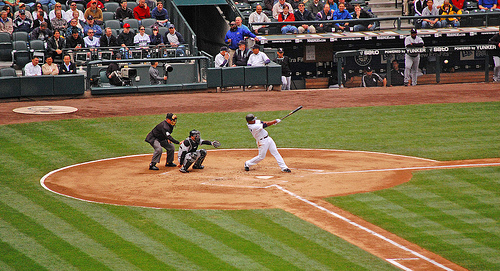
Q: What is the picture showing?
A: It is showing a field.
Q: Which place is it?
A: It is a field.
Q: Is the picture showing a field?
A: Yes, it is showing a field.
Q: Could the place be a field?
A: Yes, it is a field.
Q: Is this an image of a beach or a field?
A: It is showing a field.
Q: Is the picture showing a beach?
A: No, the picture is showing a field.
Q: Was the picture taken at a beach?
A: No, the picture was taken in a field.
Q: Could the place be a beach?
A: No, it is a field.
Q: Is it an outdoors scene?
A: Yes, it is outdoors.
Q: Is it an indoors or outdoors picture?
A: It is outdoors.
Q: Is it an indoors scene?
A: No, it is outdoors.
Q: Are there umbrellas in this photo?
A: No, there are no umbrellas.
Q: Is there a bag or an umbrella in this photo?
A: No, there are no umbrellas or bags.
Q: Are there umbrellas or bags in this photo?
A: No, there are no umbrellas or bags.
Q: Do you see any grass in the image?
A: Yes, there is grass.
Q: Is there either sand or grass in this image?
A: Yes, there is grass.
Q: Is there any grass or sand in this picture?
A: Yes, there is grass.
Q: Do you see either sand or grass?
A: Yes, there is grass.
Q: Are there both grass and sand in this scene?
A: No, there is grass but no sand.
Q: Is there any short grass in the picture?
A: Yes, there is short grass.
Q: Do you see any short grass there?
A: Yes, there is short grass.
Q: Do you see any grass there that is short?
A: Yes, there is grass that is short.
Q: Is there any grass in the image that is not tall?
A: Yes, there is short grass.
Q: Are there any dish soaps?
A: No, there are no dish soaps.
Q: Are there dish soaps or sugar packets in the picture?
A: No, there are no dish soaps or sugar packets.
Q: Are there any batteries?
A: No, there are no batteries.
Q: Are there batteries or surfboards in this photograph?
A: No, there are no batteries or surfboards.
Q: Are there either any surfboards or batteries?
A: No, there are no batteries or surfboards.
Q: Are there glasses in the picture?
A: No, there are no glasses.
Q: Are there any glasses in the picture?
A: No, there are no glasses.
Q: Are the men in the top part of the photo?
A: Yes, the men are in the top of the image.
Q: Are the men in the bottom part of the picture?
A: No, the men are in the top of the image.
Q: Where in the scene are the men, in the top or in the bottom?
A: The men are in the top of the image.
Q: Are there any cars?
A: No, there are no cars.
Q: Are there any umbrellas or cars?
A: No, there are no cars or umbrellas.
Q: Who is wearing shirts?
A: The people are wearing shirts.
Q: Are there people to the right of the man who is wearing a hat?
A: Yes, there are people to the right of the man.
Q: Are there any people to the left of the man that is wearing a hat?
A: No, the people are to the right of the man.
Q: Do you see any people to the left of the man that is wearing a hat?
A: No, the people are to the right of the man.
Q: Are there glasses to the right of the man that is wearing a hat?
A: No, there are people to the right of the man.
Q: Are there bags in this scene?
A: No, there are no bags.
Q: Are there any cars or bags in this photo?
A: No, there are no bags or cars.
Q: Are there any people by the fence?
A: Yes, there is a person by the fence.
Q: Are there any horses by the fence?
A: No, there is a person by the fence.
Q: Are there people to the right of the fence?
A: Yes, there is a person to the right of the fence.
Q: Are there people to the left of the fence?
A: No, the person is to the right of the fence.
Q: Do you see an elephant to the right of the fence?
A: No, there is a person to the right of the fence.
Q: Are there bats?
A: Yes, there is a bat.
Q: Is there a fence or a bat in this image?
A: Yes, there is a bat.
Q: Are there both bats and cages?
A: No, there is a bat but no cages.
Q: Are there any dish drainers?
A: No, there are no dish drainers.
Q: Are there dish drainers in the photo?
A: No, there are no dish drainers.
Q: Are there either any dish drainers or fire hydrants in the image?
A: No, there are no dish drainers or fire hydrants.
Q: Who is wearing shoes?
A: The umpire is wearing shoes.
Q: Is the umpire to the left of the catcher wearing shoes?
A: Yes, the umpire is wearing shoes.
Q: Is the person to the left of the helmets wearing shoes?
A: Yes, the umpire is wearing shoes.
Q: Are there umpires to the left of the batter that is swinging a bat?
A: Yes, there is an umpire to the left of the batter.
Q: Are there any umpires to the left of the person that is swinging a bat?
A: Yes, there is an umpire to the left of the batter.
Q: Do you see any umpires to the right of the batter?
A: No, the umpire is to the left of the batter.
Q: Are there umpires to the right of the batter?
A: No, the umpire is to the left of the batter.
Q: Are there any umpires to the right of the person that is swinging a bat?
A: No, the umpire is to the left of the batter.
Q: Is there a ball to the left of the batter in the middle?
A: No, there is an umpire to the left of the batter.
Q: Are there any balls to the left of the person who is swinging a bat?
A: No, there is an umpire to the left of the batter.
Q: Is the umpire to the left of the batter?
A: Yes, the umpire is to the left of the batter.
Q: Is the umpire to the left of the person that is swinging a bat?
A: Yes, the umpire is to the left of the batter.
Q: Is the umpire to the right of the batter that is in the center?
A: No, the umpire is to the left of the batter.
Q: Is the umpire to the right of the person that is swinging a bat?
A: No, the umpire is to the left of the batter.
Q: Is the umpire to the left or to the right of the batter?
A: The umpire is to the left of the batter.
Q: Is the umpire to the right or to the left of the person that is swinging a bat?
A: The umpire is to the left of the batter.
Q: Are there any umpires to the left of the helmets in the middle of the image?
A: Yes, there is an umpire to the left of the helmets.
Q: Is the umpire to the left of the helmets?
A: Yes, the umpire is to the left of the helmets.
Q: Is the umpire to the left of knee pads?
A: No, the umpire is to the left of the helmets.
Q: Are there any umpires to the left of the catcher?
A: Yes, there is an umpire to the left of the catcher.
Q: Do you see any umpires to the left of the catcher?
A: Yes, there is an umpire to the left of the catcher.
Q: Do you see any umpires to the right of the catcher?
A: No, the umpire is to the left of the catcher.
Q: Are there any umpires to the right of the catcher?
A: No, the umpire is to the left of the catcher.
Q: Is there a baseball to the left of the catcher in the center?
A: No, there is an umpire to the left of the catcher.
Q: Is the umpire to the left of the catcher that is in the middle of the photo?
A: Yes, the umpire is to the left of the catcher.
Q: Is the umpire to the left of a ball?
A: No, the umpire is to the left of the catcher.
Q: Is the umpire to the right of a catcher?
A: No, the umpire is to the left of a catcher.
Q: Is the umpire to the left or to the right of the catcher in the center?
A: The umpire is to the left of the catcher.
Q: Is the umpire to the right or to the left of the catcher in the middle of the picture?
A: The umpire is to the left of the catcher.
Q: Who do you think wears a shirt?
A: The umpire wears a shirt.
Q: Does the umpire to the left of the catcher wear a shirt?
A: Yes, the umpire wears a shirt.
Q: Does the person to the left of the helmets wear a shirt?
A: Yes, the umpire wears a shirt.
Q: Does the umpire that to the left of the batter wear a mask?
A: No, the umpire wears a shirt.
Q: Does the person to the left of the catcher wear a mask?
A: No, the umpire wears a shirt.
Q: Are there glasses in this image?
A: No, there are no glasses.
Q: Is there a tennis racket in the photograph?
A: No, there are no rackets.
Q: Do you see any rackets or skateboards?
A: No, there are no rackets or skateboards.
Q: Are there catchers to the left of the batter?
A: Yes, there is a catcher to the left of the batter.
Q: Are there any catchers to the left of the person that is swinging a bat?
A: Yes, there is a catcher to the left of the batter.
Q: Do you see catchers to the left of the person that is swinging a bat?
A: Yes, there is a catcher to the left of the batter.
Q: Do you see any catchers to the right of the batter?
A: No, the catcher is to the left of the batter.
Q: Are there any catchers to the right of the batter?
A: No, the catcher is to the left of the batter.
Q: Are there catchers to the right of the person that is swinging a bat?
A: No, the catcher is to the left of the batter.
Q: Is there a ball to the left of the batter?
A: No, there is a catcher to the left of the batter.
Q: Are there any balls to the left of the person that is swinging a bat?
A: No, there is a catcher to the left of the batter.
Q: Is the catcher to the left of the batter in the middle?
A: Yes, the catcher is to the left of the batter.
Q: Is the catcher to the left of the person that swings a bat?
A: Yes, the catcher is to the left of the batter.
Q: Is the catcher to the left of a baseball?
A: No, the catcher is to the left of the batter.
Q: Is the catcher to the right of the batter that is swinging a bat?
A: No, the catcher is to the left of the batter.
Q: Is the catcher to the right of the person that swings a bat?
A: No, the catcher is to the left of the batter.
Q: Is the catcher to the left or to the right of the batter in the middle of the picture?
A: The catcher is to the left of the batter.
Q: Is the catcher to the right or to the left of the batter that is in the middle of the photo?
A: The catcher is to the left of the batter.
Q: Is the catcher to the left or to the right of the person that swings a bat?
A: The catcher is to the left of the batter.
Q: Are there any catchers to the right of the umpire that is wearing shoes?
A: Yes, there is a catcher to the right of the umpire.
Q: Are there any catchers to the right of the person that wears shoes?
A: Yes, there is a catcher to the right of the umpire.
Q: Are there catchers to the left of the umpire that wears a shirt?
A: No, the catcher is to the right of the umpire.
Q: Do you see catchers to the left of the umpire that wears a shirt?
A: No, the catcher is to the right of the umpire.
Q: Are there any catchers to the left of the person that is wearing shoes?
A: No, the catcher is to the right of the umpire.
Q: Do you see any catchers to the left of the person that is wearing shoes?
A: No, the catcher is to the right of the umpire.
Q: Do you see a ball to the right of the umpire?
A: No, there is a catcher to the right of the umpire.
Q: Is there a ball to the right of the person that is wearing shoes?
A: No, there is a catcher to the right of the umpire.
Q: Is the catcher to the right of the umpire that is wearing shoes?
A: Yes, the catcher is to the right of the umpire.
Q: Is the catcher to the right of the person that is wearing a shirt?
A: Yes, the catcher is to the right of the umpire.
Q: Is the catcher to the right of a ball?
A: No, the catcher is to the right of the umpire.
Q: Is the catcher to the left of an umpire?
A: No, the catcher is to the right of an umpire.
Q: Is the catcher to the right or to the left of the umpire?
A: The catcher is to the right of the umpire.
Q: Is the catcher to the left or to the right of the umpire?
A: The catcher is to the right of the umpire.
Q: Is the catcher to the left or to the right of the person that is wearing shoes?
A: The catcher is to the right of the umpire.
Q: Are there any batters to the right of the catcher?
A: Yes, there is a batter to the right of the catcher.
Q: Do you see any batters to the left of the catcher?
A: No, the batter is to the right of the catcher.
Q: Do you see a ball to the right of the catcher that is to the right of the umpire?
A: No, there is a batter to the right of the catcher.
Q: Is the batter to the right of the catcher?
A: Yes, the batter is to the right of the catcher.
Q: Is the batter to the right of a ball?
A: No, the batter is to the right of the catcher.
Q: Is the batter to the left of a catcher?
A: No, the batter is to the right of a catcher.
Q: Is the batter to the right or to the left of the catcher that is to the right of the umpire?
A: The batter is to the right of the catcher.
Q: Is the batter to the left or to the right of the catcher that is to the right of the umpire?
A: The batter is to the right of the catcher.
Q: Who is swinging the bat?
A: The batter is swinging the bat.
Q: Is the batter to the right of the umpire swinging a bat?
A: Yes, the batter is swinging a bat.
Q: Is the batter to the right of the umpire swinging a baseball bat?
A: No, the batter is swinging a bat.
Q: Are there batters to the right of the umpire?
A: Yes, there is a batter to the right of the umpire.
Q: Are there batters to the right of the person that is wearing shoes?
A: Yes, there is a batter to the right of the umpire.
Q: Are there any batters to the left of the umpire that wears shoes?
A: No, the batter is to the right of the umpire.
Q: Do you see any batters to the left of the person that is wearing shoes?
A: No, the batter is to the right of the umpire.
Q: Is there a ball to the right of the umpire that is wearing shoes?
A: No, there is a batter to the right of the umpire.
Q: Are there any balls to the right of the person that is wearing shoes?
A: No, there is a batter to the right of the umpire.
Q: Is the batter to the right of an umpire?
A: Yes, the batter is to the right of an umpire.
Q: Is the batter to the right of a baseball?
A: No, the batter is to the right of an umpire.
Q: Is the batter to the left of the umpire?
A: No, the batter is to the right of the umpire.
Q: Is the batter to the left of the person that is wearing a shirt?
A: No, the batter is to the right of the umpire.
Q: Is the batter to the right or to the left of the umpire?
A: The batter is to the right of the umpire.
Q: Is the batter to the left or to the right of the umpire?
A: The batter is to the right of the umpire.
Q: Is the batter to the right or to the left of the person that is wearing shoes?
A: The batter is to the right of the umpire.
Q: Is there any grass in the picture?
A: Yes, there is grass.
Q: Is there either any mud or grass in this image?
A: Yes, there is grass.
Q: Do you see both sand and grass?
A: No, there is grass but no sand.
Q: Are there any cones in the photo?
A: No, there are no cones.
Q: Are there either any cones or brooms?
A: No, there are no cones or brooms.